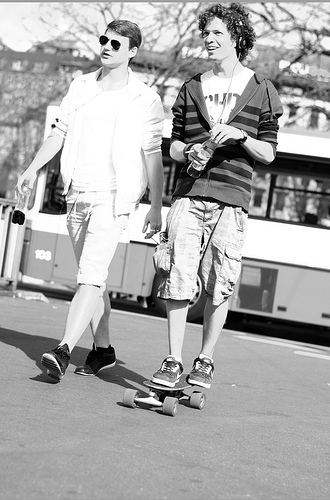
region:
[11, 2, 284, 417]
Two guys wandering around.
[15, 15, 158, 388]
Young man walking on a sidewalk.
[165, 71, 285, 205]
Young man wearing a striped hooded sweatshirt.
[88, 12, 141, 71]
Young man with dark straight hair.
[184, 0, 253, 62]
Young man with long curly hair.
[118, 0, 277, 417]
Young man with curly hair is on a skateboard.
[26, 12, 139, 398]
Young man with sunglasses walking.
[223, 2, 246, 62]
Boy with a headphone on the head.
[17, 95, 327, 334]
A big transit bus behind the boys.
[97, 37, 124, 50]
sunglasses on the man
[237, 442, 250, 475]
the street is concrete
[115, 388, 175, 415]
wheels of the skateboard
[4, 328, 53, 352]
shadow of the man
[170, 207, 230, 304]
shorts on the man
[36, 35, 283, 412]
two men are in the street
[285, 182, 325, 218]
window of the building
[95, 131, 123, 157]
the clothes are white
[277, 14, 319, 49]
branches on the tree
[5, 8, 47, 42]
the sky is clear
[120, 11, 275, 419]
A guy on a skateboard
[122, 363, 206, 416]
A skateboard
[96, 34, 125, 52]
A pair of sunglasses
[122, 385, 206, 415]
Large wheels on a skateboard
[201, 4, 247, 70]
Dark colored headphones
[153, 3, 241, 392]
A guy with curly hair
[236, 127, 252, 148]
A wrist watch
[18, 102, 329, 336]
A bus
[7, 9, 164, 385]
A man walking beside a guy on a skateboard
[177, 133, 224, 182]
A drink bottle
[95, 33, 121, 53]
black glasses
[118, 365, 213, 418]
skateboard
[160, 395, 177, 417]
the skateboard's front left wheel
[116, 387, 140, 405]
the skateboard's front right wheel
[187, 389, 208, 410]
the skateboard's back left wheel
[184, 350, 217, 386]
the boy's left foot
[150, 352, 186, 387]
the boy's right foot with shoe on it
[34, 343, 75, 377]
black left shoe on the man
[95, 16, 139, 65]
the man's head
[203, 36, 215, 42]
the man's nose on his face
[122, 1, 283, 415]
man riding on a skateboard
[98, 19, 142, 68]
head with short hair and sunglasses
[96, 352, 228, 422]
A boy on a skateboard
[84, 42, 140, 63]
A man with black glasses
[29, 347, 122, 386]
Man with black shoes